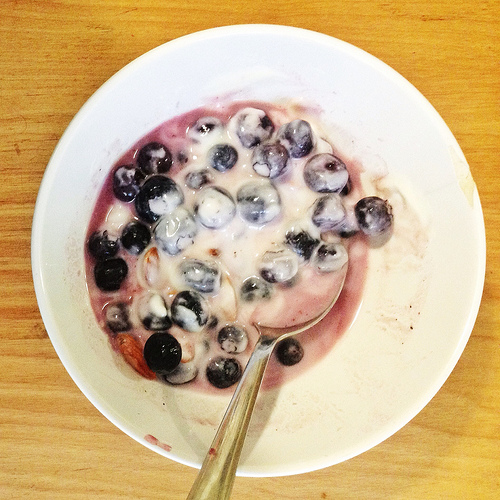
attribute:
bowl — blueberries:
[52, 82, 450, 420]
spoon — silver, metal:
[172, 227, 354, 494]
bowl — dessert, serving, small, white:
[28, 24, 493, 478]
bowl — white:
[59, 41, 484, 481]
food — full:
[6, 25, 497, 488]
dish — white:
[31, 22, 485, 476]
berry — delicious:
[225, 105, 280, 151]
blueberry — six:
[300, 153, 354, 195]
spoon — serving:
[182, 241, 374, 498]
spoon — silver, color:
[186, 239, 347, 497]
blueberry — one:
[231, 126, 315, 207]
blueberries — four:
[104, 156, 432, 378]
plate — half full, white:
[31, 25, 487, 481]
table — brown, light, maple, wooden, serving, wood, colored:
[6, 4, 493, 494]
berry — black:
[143, 330, 185, 381]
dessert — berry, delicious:
[67, 90, 443, 446]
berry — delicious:
[352, 193, 398, 243]